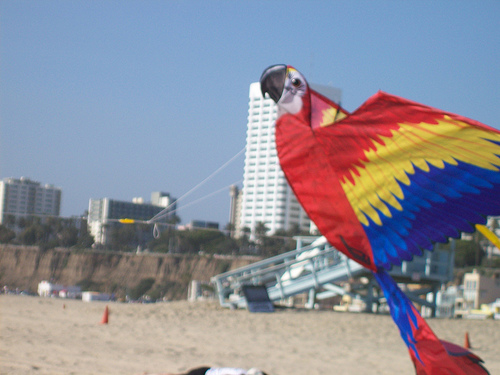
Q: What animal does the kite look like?
A: Parrot.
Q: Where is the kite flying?
A: On the beach.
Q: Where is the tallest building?
A: Behind the parrot kite.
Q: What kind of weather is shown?
A: Sunny and clear.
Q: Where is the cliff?
A: At the edge of the beach.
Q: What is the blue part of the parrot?
A: Feathers.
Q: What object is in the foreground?
A: A kite.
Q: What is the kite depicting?
A: A parrot.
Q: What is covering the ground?
A: Sand.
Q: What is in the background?
A: Buildings.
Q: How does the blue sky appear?
A: Cloudless.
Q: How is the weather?
A: Clear.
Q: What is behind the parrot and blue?
A: Stairs.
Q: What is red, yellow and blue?
A: The kite.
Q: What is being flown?
A: A parrot kite.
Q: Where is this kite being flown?
A: The beach.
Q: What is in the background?
A: Trees, buildings and sand.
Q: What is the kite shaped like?
A: A colorful parrot.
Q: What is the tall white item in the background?
A: A building.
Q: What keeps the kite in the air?
A: Wind.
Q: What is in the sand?
A: Orange cones.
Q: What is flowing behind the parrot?
A: A long tail.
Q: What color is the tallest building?
A: White.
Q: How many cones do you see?
A: One.